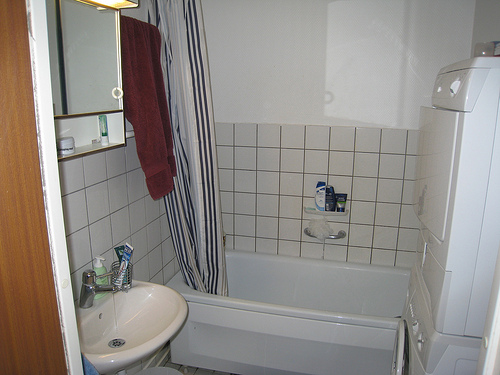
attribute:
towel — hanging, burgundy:
[119, 14, 178, 201]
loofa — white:
[307, 217, 334, 243]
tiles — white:
[58, 121, 422, 285]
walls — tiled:
[46, 0, 476, 375]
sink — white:
[72, 279, 190, 374]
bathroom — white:
[45, 0, 499, 374]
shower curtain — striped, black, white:
[145, 0, 229, 297]